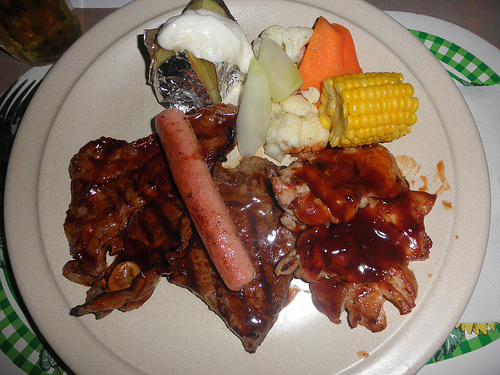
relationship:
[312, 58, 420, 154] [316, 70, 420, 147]
corn on corn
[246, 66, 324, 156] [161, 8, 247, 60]
potato with cream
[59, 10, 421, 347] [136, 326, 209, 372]
food on plate